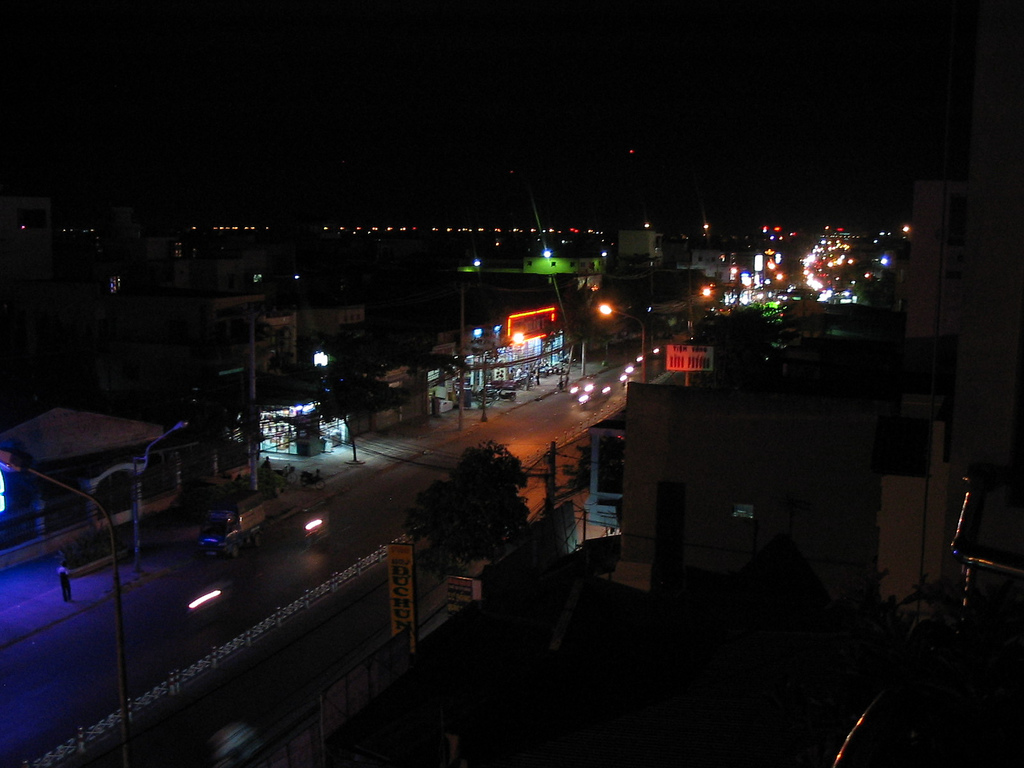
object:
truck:
[191, 501, 275, 557]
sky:
[0, 4, 1024, 276]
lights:
[579, 298, 636, 333]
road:
[55, 242, 824, 762]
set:
[200, 298, 341, 463]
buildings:
[589, 367, 958, 625]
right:
[822, 31, 991, 714]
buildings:
[9, 393, 198, 560]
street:
[16, 354, 645, 755]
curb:
[102, 494, 223, 559]